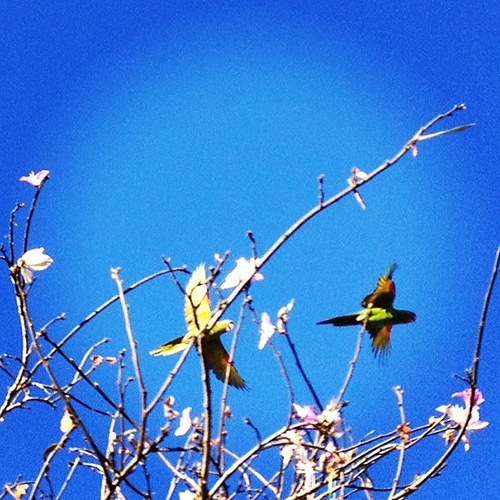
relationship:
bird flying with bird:
[145, 259, 250, 395] [311, 270, 422, 372]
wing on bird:
[359, 263, 396, 305] [313, 261, 415, 367]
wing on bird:
[363, 321, 395, 372] [313, 261, 415, 367]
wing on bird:
[201, 339, 253, 393] [313, 261, 415, 367]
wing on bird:
[182, 260, 212, 332] [313, 261, 415, 367]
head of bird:
[398, 307, 416, 323] [313, 261, 415, 367]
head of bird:
[213, 313, 239, 337] [147, 262, 252, 396]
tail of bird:
[148, 334, 191, 361] [147, 262, 252, 396]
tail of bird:
[317, 310, 365, 326] [313, 261, 415, 367]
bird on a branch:
[316, 272, 416, 369] [352, 280, 371, 386]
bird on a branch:
[147, 262, 252, 396] [178, 295, 234, 368]